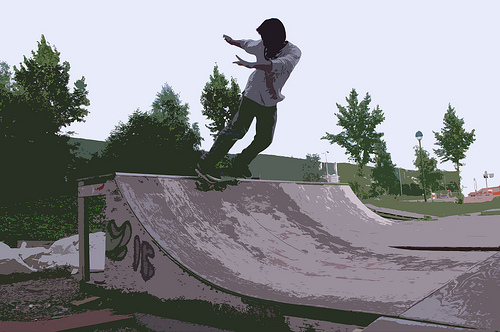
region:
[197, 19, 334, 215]
the man is skateboarding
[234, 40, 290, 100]
the shirt is white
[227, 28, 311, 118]
the shirt is white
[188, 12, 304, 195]
boy on skate ramp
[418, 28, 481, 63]
white clouds in blue sky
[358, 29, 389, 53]
white clouds in blue sky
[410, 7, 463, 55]
white clouds in blue sky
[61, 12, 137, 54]
white clouds in blue sky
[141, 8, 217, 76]
white clouds in blue sky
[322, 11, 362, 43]
white clouds in blue sky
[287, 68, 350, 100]
white clouds in blue sky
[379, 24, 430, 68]
white clouds in blue sky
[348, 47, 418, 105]
white clouds in blue sky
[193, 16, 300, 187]
a man on a skateboard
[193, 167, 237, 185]
a guy's skateboard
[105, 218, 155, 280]
graffiti on a skateboard ramp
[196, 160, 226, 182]
a skater's right shoe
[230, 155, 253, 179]
a skater's left shoe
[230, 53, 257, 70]
a skater's left hand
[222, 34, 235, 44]
a skater's right hand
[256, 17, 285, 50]
a skater's face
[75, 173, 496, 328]
a wood skateboard ramp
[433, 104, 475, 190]
a tall green tree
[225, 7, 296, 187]
man doing trick on ramp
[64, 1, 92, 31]
white clouds in blue sky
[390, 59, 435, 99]
white clouds in blue sky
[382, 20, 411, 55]
white clouds in blue sky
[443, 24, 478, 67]
white clouds in blue sky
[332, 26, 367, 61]
white clouds in blue sky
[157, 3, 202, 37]
white clouds in blue sky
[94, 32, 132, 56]
white clouds in blue sky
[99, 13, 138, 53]
white clouds in blue sky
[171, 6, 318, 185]
young man doing trick on ramp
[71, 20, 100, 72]
white clouds in blue sky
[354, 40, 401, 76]
white clouds in blue sky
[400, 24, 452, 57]
white clouds in blue sky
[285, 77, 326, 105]
white clouds in blue sky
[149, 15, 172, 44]
white clouds in blue sky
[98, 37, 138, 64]
white clouds in blue sky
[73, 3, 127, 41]
white clouds in blue sky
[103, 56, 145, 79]
white clouds in blue sky